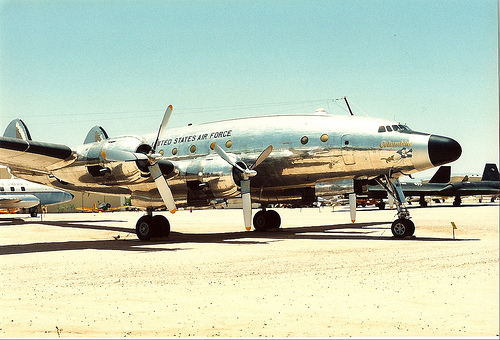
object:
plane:
[0, 95, 462, 240]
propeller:
[208, 145, 277, 232]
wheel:
[388, 218, 415, 239]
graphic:
[378, 146, 419, 168]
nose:
[398, 128, 462, 173]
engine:
[103, 105, 274, 204]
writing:
[152, 128, 236, 147]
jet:
[365, 163, 499, 208]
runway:
[1, 199, 499, 338]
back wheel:
[134, 216, 172, 242]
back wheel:
[252, 208, 276, 235]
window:
[376, 125, 389, 133]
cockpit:
[361, 117, 413, 151]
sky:
[0, 1, 500, 96]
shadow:
[1, 219, 482, 257]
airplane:
[1, 165, 77, 221]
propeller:
[98, 104, 180, 214]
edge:
[1, 136, 76, 164]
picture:
[0, 0, 500, 340]